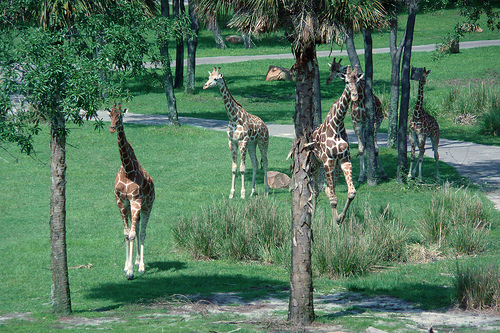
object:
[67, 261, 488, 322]
shadow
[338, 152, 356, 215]
leg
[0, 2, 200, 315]
tree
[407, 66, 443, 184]
giraffe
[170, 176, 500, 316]
bushes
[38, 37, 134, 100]
leaves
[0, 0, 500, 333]
ground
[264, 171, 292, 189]
rock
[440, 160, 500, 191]
shadows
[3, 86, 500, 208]
pavement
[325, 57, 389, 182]
giraffe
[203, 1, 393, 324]
tree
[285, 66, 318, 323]
tree trunk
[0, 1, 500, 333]
park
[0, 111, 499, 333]
lawn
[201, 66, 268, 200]
giraffe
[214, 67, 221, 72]
horns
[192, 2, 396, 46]
leaves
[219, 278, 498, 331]
patches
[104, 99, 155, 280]
giraffe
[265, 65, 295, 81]
rock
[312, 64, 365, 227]
giraffe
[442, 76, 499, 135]
bushes